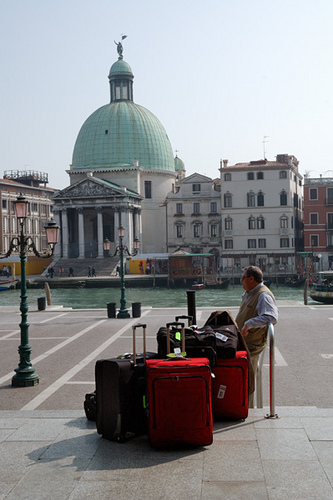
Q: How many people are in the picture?
A: One.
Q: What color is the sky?
A: Blue.